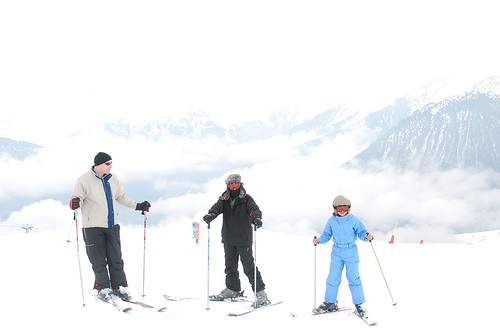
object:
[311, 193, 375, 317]
kid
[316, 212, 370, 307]
outfit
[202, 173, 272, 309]
skier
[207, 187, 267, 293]
outfit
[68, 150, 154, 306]
man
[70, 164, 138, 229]
coat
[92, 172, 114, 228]
shirt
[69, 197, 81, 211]
glove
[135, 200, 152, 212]
glove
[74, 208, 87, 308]
pole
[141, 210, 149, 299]
pole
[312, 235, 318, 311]
pole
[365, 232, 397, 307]
pole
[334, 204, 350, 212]
goggles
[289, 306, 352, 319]
skis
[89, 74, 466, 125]
snow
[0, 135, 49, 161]
mountains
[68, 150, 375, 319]
group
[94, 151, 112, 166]
hat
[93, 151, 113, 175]
head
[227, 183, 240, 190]
goggles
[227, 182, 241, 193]
face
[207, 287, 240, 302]
boots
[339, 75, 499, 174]
mountain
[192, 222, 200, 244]
flag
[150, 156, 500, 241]
cloud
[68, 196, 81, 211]
hand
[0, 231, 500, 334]
snow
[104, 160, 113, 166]
sunglasses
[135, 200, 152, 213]
hand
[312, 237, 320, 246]
hand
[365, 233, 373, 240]
hand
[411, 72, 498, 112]
snow